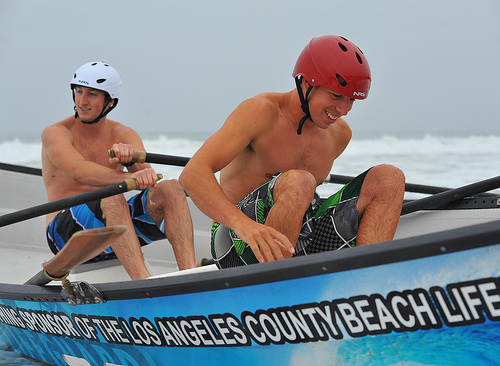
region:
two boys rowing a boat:
[26, 23, 415, 288]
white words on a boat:
[67, 306, 258, 357]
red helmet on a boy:
[285, 25, 373, 132]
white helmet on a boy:
[63, 53, 132, 138]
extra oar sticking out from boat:
[29, 219, 124, 315]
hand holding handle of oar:
[106, 136, 185, 168]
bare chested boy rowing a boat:
[181, 28, 413, 260]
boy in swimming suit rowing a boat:
[20, 58, 185, 267]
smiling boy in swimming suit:
[178, 18, 406, 255]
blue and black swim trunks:
[48, 178, 198, 273]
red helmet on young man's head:
[291, 30, 380, 99]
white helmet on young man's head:
[66, 63, 125, 99]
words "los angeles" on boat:
[119, 316, 249, 347]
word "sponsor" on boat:
[11, 307, 75, 338]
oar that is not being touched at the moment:
[13, 220, 127, 299]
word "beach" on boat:
[329, 285, 441, 335]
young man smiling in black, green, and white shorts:
[188, 30, 418, 252]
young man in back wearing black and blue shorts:
[38, 63, 186, 281]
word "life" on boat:
[435, 280, 497, 330]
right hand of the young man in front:
[228, 210, 304, 267]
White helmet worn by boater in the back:
[68, 57, 118, 122]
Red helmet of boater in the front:
[290, 32, 370, 132]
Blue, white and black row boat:
[0, 155, 495, 356]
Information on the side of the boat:
[0, 270, 490, 350]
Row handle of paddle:
[1, 168, 163, 226]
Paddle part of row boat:
[31, 225, 121, 277]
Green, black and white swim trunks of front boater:
[225, 165, 370, 260]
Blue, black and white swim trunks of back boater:
[42, 177, 163, 264]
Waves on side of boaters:
[0, 130, 497, 181]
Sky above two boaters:
[0, 5, 498, 135]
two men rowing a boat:
[20, 21, 417, 358]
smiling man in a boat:
[176, 27, 418, 288]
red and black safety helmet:
[285, 25, 380, 90]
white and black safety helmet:
[65, 46, 120, 97]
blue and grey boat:
[0, 210, 495, 350]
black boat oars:
[10, 136, 180, 231]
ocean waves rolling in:
[395, 115, 491, 165]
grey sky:
[150, 25, 230, 100]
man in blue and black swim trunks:
[30, 45, 191, 310]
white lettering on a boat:
[0, 283, 487, 346]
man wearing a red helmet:
[273, 23, 388, 118]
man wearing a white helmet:
[62, 41, 155, 130]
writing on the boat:
[0, 270, 496, 362]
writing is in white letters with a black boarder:
[0, 264, 494, 362]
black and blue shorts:
[29, 165, 203, 265]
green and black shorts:
[191, 165, 438, 267]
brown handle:
[99, 139, 162, 169]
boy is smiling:
[59, 60, 153, 135]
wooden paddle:
[8, 213, 139, 307]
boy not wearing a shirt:
[17, 59, 174, 220]